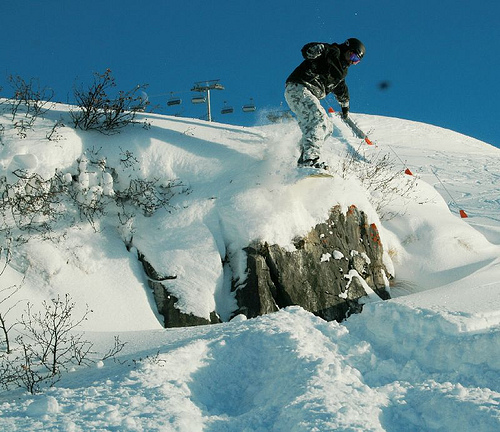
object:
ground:
[6, 108, 481, 415]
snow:
[7, 136, 500, 431]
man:
[283, 37, 365, 167]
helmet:
[343, 38, 364, 61]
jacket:
[287, 42, 350, 107]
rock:
[123, 205, 395, 327]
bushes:
[63, 67, 158, 134]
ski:
[220, 90, 235, 115]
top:
[4, 3, 499, 133]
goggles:
[346, 50, 360, 66]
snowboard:
[296, 160, 335, 177]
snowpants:
[284, 80, 335, 160]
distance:
[1, 63, 500, 129]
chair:
[192, 87, 205, 104]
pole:
[206, 89, 213, 123]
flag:
[459, 208, 470, 219]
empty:
[167, 93, 181, 105]